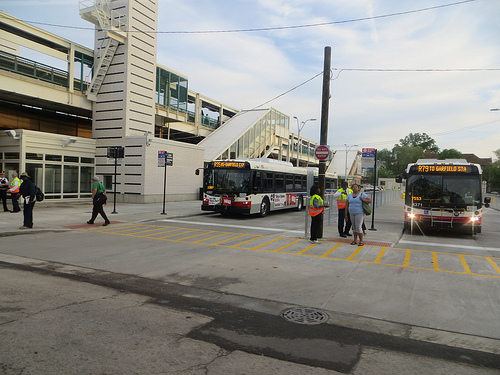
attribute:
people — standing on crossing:
[304, 176, 374, 252]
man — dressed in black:
[15, 168, 45, 229]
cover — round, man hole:
[279, 302, 329, 327]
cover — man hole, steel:
[280, 301, 330, 326]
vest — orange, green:
[307, 193, 332, 222]